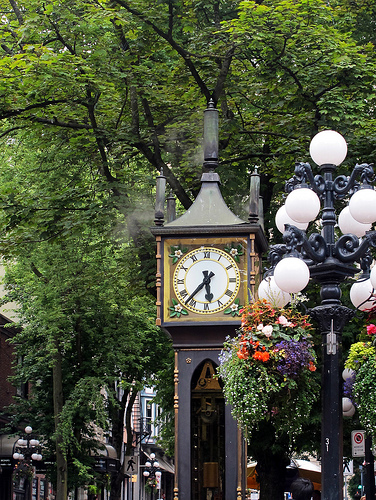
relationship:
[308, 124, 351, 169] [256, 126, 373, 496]
orb on lamp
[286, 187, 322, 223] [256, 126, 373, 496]
orb on lamp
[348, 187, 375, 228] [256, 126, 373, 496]
orb on lamp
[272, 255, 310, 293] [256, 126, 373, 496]
orb on lamp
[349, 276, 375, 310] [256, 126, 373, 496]
orb on lamp